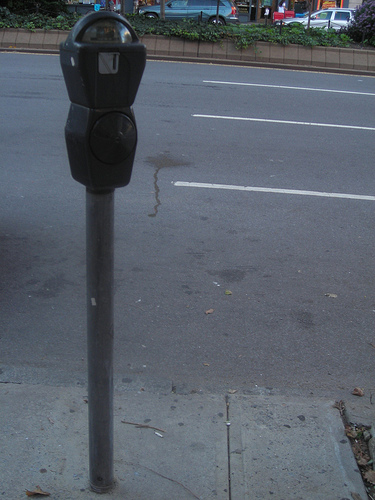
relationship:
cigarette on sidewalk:
[152, 427, 162, 439] [0, 383, 369, 499]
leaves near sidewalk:
[345, 423, 373, 490] [0, 383, 369, 499]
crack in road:
[147, 168, 164, 220] [3, 49, 373, 394]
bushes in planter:
[1, 8, 372, 49] [1, 26, 372, 73]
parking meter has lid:
[56, 12, 146, 190] [87, 109, 136, 167]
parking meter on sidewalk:
[56, 12, 146, 190] [0, 383, 369, 499]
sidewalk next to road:
[0, 383, 369, 499] [3, 49, 373, 394]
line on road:
[168, 176, 374, 205] [3, 49, 373, 394]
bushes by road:
[1, 8, 372, 49] [3, 49, 373, 394]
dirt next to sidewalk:
[346, 423, 373, 496] [0, 383, 369, 499]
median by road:
[0, 23, 371, 75] [3, 49, 373, 394]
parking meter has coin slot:
[56, 12, 146, 190] [111, 50, 117, 71]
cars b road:
[141, 0, 242, 29] [3, 49, 373, 394]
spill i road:
[146, 152, 182, 217] [3, 49, 373, 394]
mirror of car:
[308, 13, 315, 21] [279, 7, 355, 32]